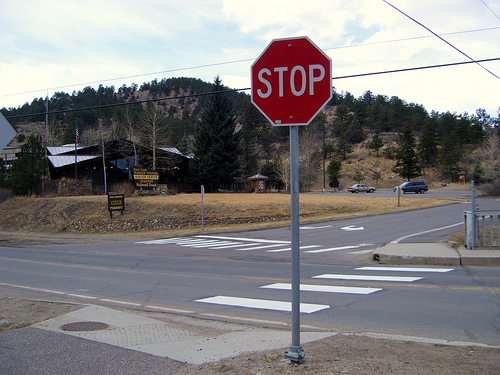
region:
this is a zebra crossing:
[313, 270, 361, 299]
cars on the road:
[344, 177, 426, 195]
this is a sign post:
[243, 32, 333, 129]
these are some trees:
[366, 107, 443, 161]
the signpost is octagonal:
[251, 36, 334, 129]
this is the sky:
[21, 5, 219, 57]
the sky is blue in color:
[165, 47, 197, 67]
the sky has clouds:
[38, 0, 391, 27]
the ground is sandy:
[222, 191, 280, 208]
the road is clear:
[36, 254, 496, 309]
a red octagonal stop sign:
[252, 38, 334, 130]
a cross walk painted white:
[183, 266, 465, 316]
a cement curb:
[377, 235, 443, 268]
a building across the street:
[42, 135, 284, 203]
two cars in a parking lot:
[342, 174, 440, 201]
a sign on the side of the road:
[99, 183, 136, 218]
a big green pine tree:
[189, 76, 253, 192]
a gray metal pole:
[280, 123, 317, 368]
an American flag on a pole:
[68, 118, 86, 153]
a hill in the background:
[0, 65, 499, 182]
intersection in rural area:
[38, 35, 469, 347]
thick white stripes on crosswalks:
[167, 225, 437, 325]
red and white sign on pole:
[240, 21, 360, 361]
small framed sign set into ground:
[95, 180, 140, 225]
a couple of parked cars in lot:
[316, 155, 466, 210]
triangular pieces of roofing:
[30, 122, 190, 174]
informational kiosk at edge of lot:
[225, 162, 275, 202]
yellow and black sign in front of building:
[120, 156, 185, 212]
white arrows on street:
[291, 200, 426, 240]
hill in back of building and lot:
[40, 63, 463, 238]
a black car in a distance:
[389, 177, 430, 197]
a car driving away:
[347, 180, 373, 195]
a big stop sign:
[245, 32, 343, 359]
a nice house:
[0, 140, 270, 199]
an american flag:
[68, 119, 82, 166]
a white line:
[195, 290, 330, 325]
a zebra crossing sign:
[196, 256, 452, 334]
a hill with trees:
[36, 72, 457, 137]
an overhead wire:
[11, 45, 498, 125]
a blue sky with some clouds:
[6, 1, 496, 124]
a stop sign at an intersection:
[246, 36, 338, 374]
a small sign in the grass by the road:
[100, 188, 130, 220]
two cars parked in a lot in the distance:
[346, 173, 436, 208]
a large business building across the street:
[34, 134, 199, 210]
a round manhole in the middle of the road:
[41, 313, 117, 345]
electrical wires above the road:
[384, 15, 498, 92]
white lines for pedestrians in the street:
[153, 229, 357, 269]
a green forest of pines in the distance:
[352, 91, 468, 171]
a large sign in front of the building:
[129, 163, 166, 198]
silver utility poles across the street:
[457, 187, 497, 256]